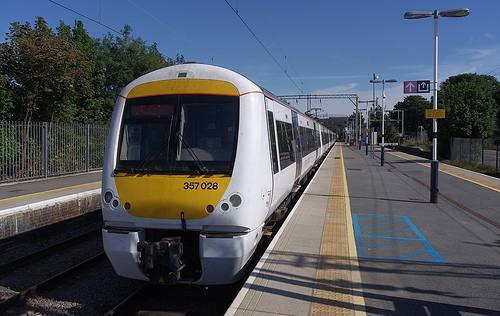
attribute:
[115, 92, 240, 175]
windows — small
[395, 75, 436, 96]
sign — yellow, black 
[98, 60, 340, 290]
light rail — yellow , white 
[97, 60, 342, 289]
train — white , yellow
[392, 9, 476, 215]
light post — tall, silver, for light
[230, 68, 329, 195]
train — white 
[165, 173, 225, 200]
numbers — black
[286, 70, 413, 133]
clouds — white 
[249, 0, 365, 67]
sky — blue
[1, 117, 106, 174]
fence — silver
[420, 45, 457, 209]
post — for light, tall, silver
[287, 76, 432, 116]
cloud — white 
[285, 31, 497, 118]
clouds — white 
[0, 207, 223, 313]
tracks — metal 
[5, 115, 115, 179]
fence — grey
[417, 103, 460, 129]
sign — Yellow 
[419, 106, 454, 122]
sign — Yellow 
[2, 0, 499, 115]
sky — blue 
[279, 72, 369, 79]
cloud — white 